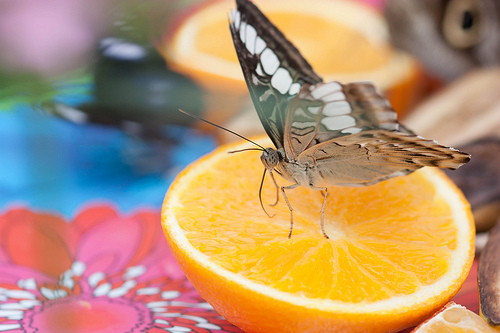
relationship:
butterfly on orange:
[207, 2, 472, 231] [166, 137, 480, 332]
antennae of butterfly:
[181, 104, 265, 155] [207, 2, 472, 231]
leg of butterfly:
[278, 183, 298, 241] [207, 2, 472, 231]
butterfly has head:
[207, 2, 472, 231] [255, 145, 282, 174]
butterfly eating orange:
[207, 2, 472, 231] [166, 137, 480, 332]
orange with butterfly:
[166, 137, 480, 332] [207, 2, 472, 231]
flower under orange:
[3, 198, 194, 330] [166, 137, 480, 332]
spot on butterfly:
[261, 50, 281, 74] [207, 2, 472, 231]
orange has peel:
[166, 137, 480, 332] [186, 252, 230, 307]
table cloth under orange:
[6, 88, 195, 331] [166, 137, 480, 332]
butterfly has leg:
[207, 2, 472, 231] [278, 183, 298, 241]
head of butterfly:
[255, 145, 282, 174] [207, 2, 472, 231]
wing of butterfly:
[224, 5, 322, 111] [207, 2, 472, 231]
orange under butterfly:
[166, 137, 480, 332] [207, 2, 472, 231]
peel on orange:
[186, 252, 230, 307] [166, 137, 480, 332]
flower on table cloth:
[3, 198, 194, 330] [6, 88, 195, 331]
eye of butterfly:
[263, 155, 274, 164] [207, 2, 472, 231]